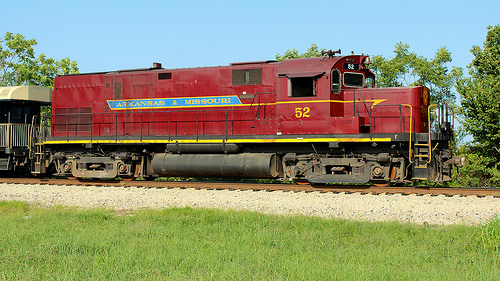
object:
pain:
[100, 115, 270, 132]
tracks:
[434, 185, 499, 197]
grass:
[0, 209, 499, 279]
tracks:
[422, 183, 499, 196]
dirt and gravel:
[266, 196, 499, 211]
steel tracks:
[403, 184, 500, 198]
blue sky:
[1, 0, 499, 32]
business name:
[106, 95, 241, 111]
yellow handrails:
[399, 101, 438, 166]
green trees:
[457, 25, 500, 186]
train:
[43, 49, 469, 186]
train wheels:
[371, 161, 397, 189]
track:
[417, 183, 499, 198]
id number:
[293, 105, 311, 121]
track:
[395, 183, 500, 198]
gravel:
[309, 193, 496, 211]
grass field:
[1, 221, 496, 280]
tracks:
[381, 184, 499, 198]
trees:
[457, 23, 500, 189]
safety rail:
[50, 107, 267, 141]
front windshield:
[342, 72, 365, 88]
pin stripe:
[243, 99, 387, 109]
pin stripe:
[43, 136, 390, 144]